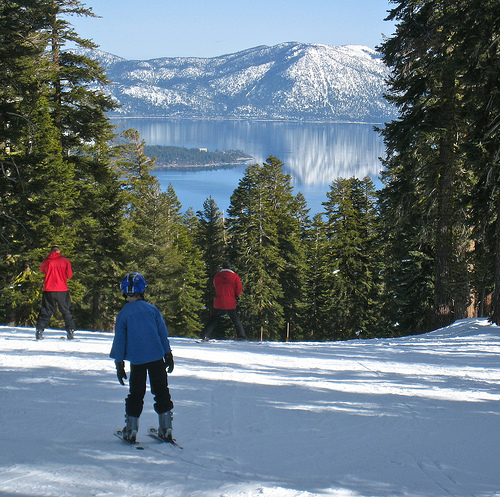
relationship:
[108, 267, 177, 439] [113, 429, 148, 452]
child on ski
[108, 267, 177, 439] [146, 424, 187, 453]
child on ski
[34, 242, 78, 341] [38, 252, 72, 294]
person wearing jacket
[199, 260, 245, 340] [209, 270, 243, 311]
person wearing jacket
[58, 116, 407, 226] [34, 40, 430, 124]
lake surrounded by mountain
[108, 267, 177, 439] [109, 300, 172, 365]
child wearing jacket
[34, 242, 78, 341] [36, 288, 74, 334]
person wearing pants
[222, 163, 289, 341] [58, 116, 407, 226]
tree near lake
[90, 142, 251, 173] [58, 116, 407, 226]
islet in lake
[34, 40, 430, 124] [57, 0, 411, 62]
mountain up against sky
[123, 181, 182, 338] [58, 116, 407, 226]
tree near lake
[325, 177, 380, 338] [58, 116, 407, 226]
tree near lake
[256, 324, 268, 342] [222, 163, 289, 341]
trunk of tree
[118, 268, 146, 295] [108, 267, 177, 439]
helmet on child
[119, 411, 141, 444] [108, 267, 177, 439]
boot on child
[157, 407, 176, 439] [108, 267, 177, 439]
boot on child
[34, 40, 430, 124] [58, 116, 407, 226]
mountain reflecting in lake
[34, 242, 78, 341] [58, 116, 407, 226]
person looking at lake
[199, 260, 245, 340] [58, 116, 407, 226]
person looking at lake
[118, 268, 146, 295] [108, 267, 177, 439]
helmet of child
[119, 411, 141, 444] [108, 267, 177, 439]
boot of child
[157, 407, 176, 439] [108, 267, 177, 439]
boot of child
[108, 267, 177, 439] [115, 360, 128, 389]
child wearing glove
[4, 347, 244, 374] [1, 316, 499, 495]
shadow on ground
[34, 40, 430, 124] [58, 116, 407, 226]
mountain reflected on lake